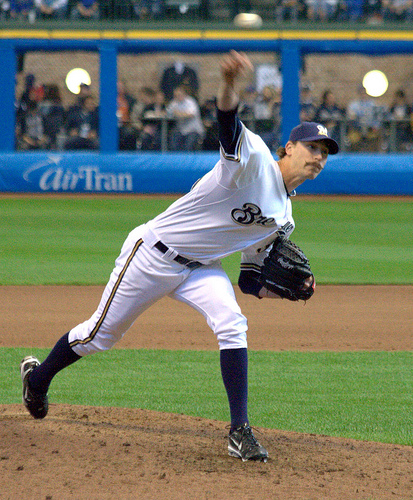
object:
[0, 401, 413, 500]
mound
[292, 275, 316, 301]
hand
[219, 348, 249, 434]
socks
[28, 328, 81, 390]
socks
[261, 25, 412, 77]
air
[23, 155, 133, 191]
ad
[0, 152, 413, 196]
wall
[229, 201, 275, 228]
logo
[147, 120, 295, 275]
shirt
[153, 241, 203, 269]
belt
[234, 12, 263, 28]
ball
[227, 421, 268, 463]
shoe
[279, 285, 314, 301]
glove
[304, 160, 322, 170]
moustache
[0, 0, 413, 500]
baseball game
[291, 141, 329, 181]
head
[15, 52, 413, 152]
spectators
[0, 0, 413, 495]
game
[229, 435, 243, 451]
nike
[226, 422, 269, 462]
foot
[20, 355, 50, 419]
foot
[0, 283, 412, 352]
dirt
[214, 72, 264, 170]
arm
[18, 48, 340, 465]
baseball player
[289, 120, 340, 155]
baseball cap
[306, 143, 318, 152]
eyes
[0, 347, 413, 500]
ground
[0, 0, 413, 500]
photo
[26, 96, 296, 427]
uniform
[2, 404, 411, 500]
dirt